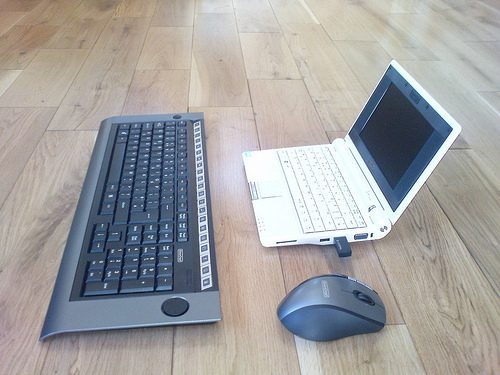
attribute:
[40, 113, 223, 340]
keyboard — black, wireless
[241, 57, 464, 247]
computer — white, open, off, small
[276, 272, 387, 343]
mouse — black, wireless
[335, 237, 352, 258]
usb — black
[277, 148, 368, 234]
keyboard — white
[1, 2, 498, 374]
floor — wood, brown, wooden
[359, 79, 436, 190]
screen — black